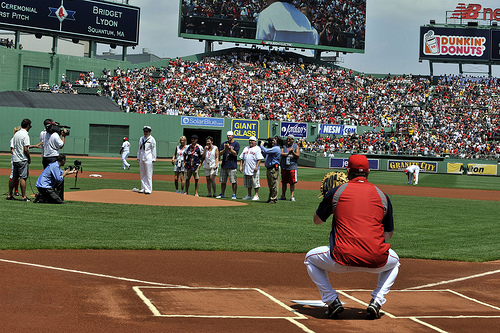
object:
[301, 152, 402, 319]
catcher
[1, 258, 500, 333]
lines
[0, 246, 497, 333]
dirt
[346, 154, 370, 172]
cap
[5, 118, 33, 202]
man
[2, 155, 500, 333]
field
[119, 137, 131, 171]
man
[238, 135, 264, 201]
man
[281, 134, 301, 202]
man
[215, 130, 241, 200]
man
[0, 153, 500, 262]
grass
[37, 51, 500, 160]
spectators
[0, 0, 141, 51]
billboard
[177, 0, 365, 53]
billboard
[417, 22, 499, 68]
billboard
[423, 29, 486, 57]
logo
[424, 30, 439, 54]
cup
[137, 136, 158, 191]
uniform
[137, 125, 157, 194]
man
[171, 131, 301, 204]
people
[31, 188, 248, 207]
pitcher's mound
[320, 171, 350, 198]
glove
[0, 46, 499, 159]
baseball stadium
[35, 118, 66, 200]
man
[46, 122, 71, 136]
camera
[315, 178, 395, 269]
shirt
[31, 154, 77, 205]
man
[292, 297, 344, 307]
home plate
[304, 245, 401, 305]
pants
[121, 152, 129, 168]
pants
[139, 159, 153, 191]
pants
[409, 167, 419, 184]
pants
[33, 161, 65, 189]
shirt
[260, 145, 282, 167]
shirt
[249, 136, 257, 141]
cap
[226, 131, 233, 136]
cap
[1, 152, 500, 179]
edge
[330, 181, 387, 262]
back